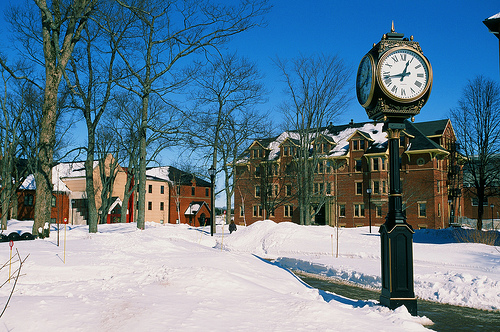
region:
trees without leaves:
[2, 1, 266, 241]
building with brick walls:
[229, 108, 467, 235]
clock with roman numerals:
[350, 20, 446, 312]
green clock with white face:
[355, 19, 450, 329]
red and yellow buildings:
[16, 132, 229, 243]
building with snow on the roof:
[221, 121, 454, 241]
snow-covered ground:
[10, 223, 498, 325]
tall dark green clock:
[349, 15, 449, 325]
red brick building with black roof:
[167, 167, 217, 227]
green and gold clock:
[344, 25, 447, 329]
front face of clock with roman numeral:
[371, 31, 442, 116]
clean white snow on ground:
[218, 263, 276, 328]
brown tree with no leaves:
[140, 14, 190, 66]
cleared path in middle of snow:
[301, 259, 406, 329]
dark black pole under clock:
[376, 147, 423, 297]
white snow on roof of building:
[268, 134, 292, 163]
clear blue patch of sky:
[298, 11, 345, 41]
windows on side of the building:
[141, 179, 176, 221]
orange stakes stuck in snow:
[2, 224, 24, 279]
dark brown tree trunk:
[33, 103, 83, 163]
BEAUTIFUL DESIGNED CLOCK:
[352, 27, 436, 316]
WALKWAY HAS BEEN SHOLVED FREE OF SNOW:
[269, 258, 499, 330]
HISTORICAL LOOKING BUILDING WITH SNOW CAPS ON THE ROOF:
[233, 112, 477, 230]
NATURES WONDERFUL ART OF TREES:
[6, 4, 189, 243]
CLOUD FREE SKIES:
[187, 7, 357, 108]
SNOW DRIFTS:
[242, 215, 332, 245]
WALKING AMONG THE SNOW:
[215, 210, 250, 241]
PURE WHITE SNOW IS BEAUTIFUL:
[61, 230, 301, 325]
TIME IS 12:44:
[366, 30, 436, 110]